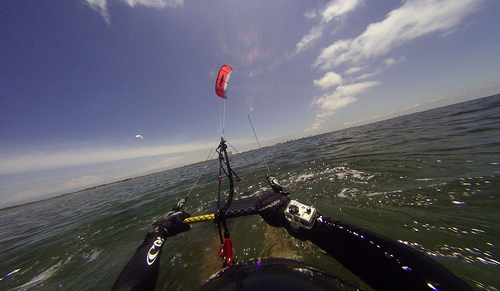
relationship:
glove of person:
[256, 190, 290, 225] [110, 192, 475, 289]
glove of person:
[152, 210, 194, 235] [110, 192, 475, 289]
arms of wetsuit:
[143, 204, 378, 258] [101, 198, 460, 289]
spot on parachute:
[219, 73, 224, 90] [111, 60, 466, 287]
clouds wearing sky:
[321, 21, 395, 114] [8, 0, 498, 170]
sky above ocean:
[8, 0, 498, 170] [366, 136, 456, 210]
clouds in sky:
[277, 0, 500, 132] [0, 2, 495, 210]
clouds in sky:
[72, 0, 201, 30] [0, 2, 495, 210]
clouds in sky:
[1, 121, 287, 215] [0, 2, 495, 210]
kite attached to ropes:
[206, 57, 236, 102] [172, 99, 280, 210]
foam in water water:
[231, 153, 395, 207] [2, 86, 496, 288]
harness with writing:
[132, 117, 340, 253] [159, 202, 309, 223]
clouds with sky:
[277, 0, 500, 132] [8, 0, 498, 170]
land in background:
[82, 192, 167, 200] [1, 180, 169, 219]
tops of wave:
[278, 170, 396, 190] [289, 167, 379, 186]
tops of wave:
[278, 170, 396, 190] [26, 249, 131, 263]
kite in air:
[214, 63, 236, 100] [2, 4, 499, 122]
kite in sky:
[214, 63, 236, 100] [2, 2, 498, 118]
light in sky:
[213, 18, 282, 118] [0, 2, 495, 210]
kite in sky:
[121, 126, 146, 152] [4, 4, 487, 154]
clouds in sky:
[277, 0, 500, 132] [7, 7, 495, 134]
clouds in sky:
[277, 0, 500, 132] [4, 4, 498, 184]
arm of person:
[105, 204, 181, 287] [88, 183, 230, 289]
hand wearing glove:
[157, 213, 185, 233] [156, 217, 188, 232]